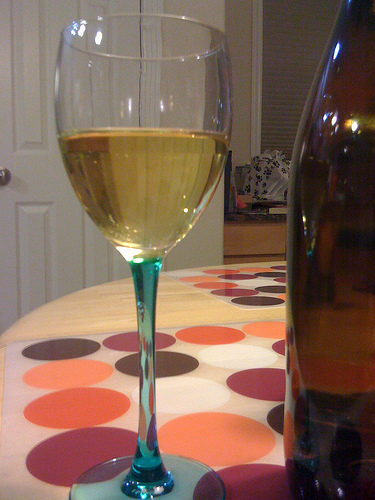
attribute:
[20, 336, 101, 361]
dot — black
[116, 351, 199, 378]
dot — black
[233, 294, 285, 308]
dot — black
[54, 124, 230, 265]
wine — white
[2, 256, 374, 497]
table — round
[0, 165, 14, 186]
knob — gold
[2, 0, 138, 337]
door — white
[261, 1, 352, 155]
shades — white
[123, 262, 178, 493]
stem — blue, skinny